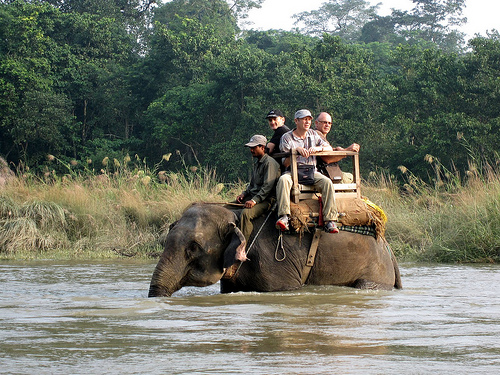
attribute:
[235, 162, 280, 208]
shirt — button down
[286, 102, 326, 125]
hat — white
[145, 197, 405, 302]
elephant — large, grayish brown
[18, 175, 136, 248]
weeds — brown, tall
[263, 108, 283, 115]
cap — ball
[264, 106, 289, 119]
hat — black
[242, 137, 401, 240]
saddle — wooden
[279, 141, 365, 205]
structure — wood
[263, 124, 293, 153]
shirt — black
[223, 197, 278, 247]
pants — green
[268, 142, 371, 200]
crate — wooden